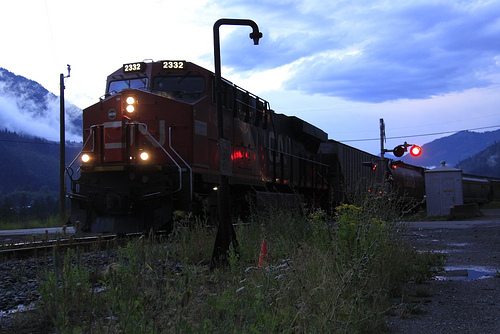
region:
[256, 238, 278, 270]
part f a graass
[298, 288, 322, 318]
part of a plant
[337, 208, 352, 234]
part of a plant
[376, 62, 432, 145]
part f a clud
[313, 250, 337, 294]
part of a plant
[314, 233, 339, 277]
part of a plant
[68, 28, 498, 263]
this is a freight train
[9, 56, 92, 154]
there is fog in the mountains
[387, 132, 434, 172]
this is a red light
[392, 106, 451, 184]
a red light is on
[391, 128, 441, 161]
a shining red light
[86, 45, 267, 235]
the train engine is red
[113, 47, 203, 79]
the numbers are illuminated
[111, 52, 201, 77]
there numbers are displayed twice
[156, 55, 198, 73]
the number of the train is 2332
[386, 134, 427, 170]
the lights are red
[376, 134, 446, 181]
the lights are red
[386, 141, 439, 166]
the lights are red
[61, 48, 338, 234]
the train is red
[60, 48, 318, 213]
the train is red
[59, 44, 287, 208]
the train is red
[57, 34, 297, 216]
the train is red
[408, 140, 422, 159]
the light is on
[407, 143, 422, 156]
the light is red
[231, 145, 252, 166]
the light is reflecting on the train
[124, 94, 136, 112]
the light is white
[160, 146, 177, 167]
the pipe is gray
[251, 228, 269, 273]
the cone is in the weeds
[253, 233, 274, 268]
the cone is orange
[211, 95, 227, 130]
the pole is black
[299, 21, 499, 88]
Heavy clouds in a blue sky.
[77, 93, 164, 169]
Four lights on the front of the train.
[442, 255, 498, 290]
A puddle of rain water.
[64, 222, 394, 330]
Weeds growing along side of the tracks.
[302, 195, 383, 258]
Yellow flowering growing in a patch.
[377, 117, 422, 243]
Red railroad signal turned on.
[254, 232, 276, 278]
Orange construction cone in the thicket.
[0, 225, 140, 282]
Trains tracks for the trains to travel.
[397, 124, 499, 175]
A mountain in the background.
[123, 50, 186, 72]
The numbers 2332 on the lead car.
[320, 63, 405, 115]
A cloud in the sky.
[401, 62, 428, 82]
A cloud in the sky.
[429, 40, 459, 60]
A cloud in the sky.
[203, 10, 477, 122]
A cloud in the sky.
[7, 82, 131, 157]
A cloud in the sky.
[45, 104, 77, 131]
A cloud in the sky.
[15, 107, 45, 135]
A cloud in the sky.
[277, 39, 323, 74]
A cloud in the sky.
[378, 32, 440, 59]
A cloud in the sky.